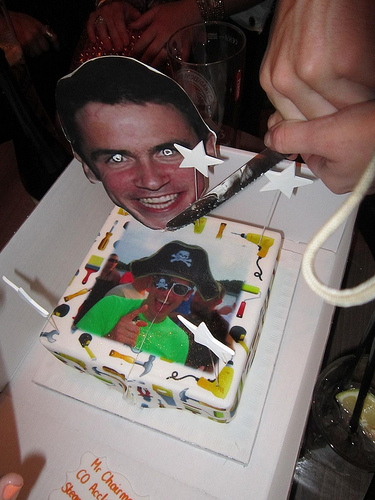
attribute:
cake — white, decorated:
[86, 217, 251, 277]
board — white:
[304, 199, 329, 216]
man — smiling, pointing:
[102, 295, 170, 366]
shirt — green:
[103, 301, 119, 326]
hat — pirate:
[149, 245, 233, 305]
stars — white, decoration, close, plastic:
[188, 135, 283, 207]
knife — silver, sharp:
[171, 180, 248, 216]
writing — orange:
[52, 456, 125, 497]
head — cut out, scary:
[67, 77, 132, 136]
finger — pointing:
[6, 472, 30, 491]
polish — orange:
[6, 484, 14, 493]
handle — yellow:
[106, 343, 145, 370]